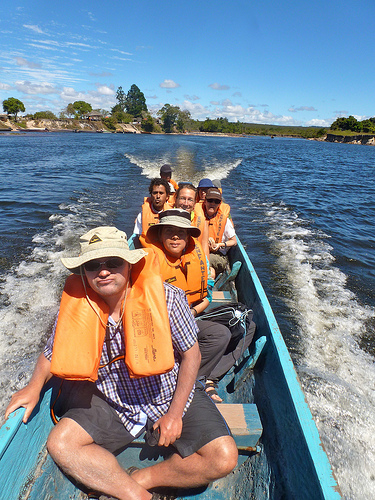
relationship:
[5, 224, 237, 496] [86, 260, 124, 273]
man wearing sunglasses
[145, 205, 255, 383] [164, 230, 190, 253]
woman has neutral expression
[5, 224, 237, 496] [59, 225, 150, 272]
man wearing a hat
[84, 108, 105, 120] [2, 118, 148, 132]
tent on shore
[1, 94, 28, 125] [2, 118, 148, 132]
tree on shore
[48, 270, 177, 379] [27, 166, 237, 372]
lifevest on all people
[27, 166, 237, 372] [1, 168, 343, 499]
people are on boat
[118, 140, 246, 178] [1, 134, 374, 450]
waves in water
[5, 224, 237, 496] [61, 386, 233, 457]
man wearing shorts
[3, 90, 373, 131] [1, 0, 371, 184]
trees in background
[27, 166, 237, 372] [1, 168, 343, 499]
people in boat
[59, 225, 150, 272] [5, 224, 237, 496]
hat on man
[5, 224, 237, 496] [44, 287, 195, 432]
man wearing plaid shirt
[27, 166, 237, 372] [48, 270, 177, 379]
people wearing lifevests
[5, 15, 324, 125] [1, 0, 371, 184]
clouds in sky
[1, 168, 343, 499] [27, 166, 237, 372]
boat holding people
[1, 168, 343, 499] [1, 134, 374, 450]
boat in water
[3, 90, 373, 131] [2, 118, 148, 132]
trees on shore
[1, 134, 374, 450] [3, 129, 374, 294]
canoe in river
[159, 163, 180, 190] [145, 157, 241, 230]
person in back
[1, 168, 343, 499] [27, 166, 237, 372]
boat holds people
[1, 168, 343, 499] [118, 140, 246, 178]
boat creating waves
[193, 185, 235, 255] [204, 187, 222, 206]
person wears brown hat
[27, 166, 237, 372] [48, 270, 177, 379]
people each wear a lifevest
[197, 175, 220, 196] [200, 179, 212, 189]
person wearing blue hat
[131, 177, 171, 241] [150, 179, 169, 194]
man has black hair